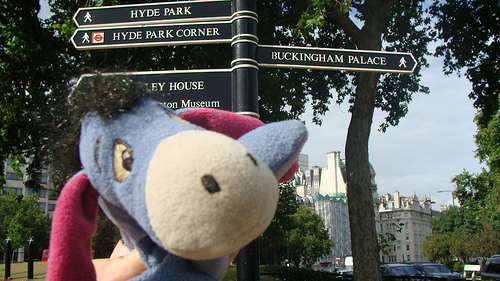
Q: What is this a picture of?
A: Eeyore.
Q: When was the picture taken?
A: Daytime.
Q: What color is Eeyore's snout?
A: White.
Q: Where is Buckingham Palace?
A: To the right.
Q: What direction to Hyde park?
A: Left.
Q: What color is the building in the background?
A: White.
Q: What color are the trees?
A: Green.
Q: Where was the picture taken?
A: England.